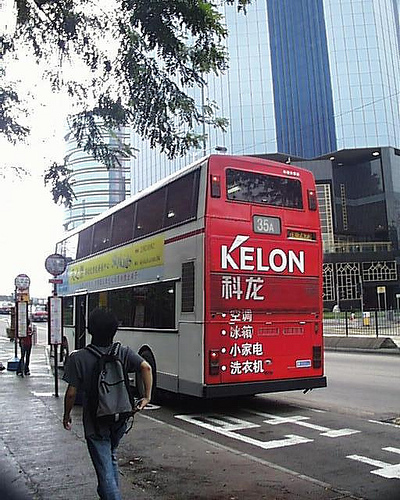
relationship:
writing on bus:
[219, 273, 271, 371] [43, 153, 327, 404]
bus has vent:
[43, 153, 327, 404] [181, 261, 194, 310]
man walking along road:
[60, 303, 152, 499] [0, 314, 399, 499]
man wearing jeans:
[60, 303, 152, 499] [82, 420, 131, 496]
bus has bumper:
[43, 153, 327, 404] [202, 376, 327, 399]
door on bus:
[66, 286, 99, 366] [56, 143, 341, 408]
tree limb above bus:
[0, 1, 258, 209] [43, 153, 327, 404]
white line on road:
[287, 397, 397, 447] [2, 305, 394, 490]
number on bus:
[250, 218, 271, 239] [16, 153, 348, 459]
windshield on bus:
[220, 183, 306, 208] [43, 153, 327, 404]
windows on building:
[291, 76, 347, 122] [117, 1, 394, 197]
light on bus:
[207, 346, 220, 374] [43, 153, 327, 404]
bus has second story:
[43, 153, 327, 404] [58, 192, 191, 238]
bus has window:
[43, 153, 327, 404] [136, 276, 179, 333]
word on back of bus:
[218, 232, 307, 276] [79, 206, 324, 401]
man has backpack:
[64, 310, 154, 492] [95, 355, 132, 422]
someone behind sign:
[15, 317, 34, 380] [14, 299, 30, 339]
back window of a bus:
[222, 164, 304, 210] [43, 153, 327, 404]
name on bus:
[193, 240, 313, 290] [21, 138, 326, 454]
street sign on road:
[214, 408, 398, 489] [2, 305, 394, 490]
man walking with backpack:
[60, 303, 152, 499] [82, 341, 139, 432]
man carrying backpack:
[60, 303, 152, 499] [77, 339, 144, 439]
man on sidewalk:
[64, 310, 154, 492] [115, 413, 331, 499]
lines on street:
[171, 403, 369, 468] [6, 311, 399, 490]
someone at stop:
[17, 317, 35, 373] [15, 256, 64, 396]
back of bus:
[200, 150, 338, 394] [43, 153, 327, 404]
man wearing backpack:
[64, 310, 154, 492] [83, 343, 135, 430]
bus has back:
[43, 153, 327, 404] [211, 153, 320, 395]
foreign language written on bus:
[218, 271, 270, 378] [43, 153, 327, 404]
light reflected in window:
[166, 207, 177, 219] [165, 165, 201, 227]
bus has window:
[174, 180, 287, 314] [58, 283, 179, 335]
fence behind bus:
[311, 300, 399, 341] [38, 141, 315, 406]